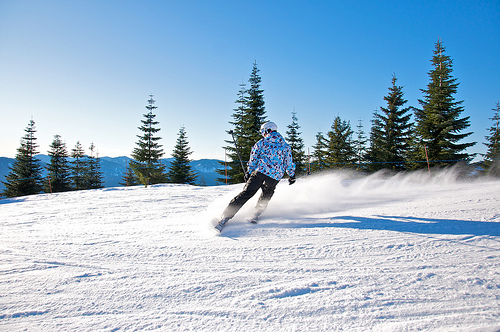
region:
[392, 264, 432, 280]
part of a snowy landscape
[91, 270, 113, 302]
part of a snowy surface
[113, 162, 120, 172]
section of a hilly land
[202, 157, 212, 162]
top part of a mountain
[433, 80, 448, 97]
leaves of a tree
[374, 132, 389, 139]
branches of a tree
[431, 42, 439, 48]
upper part of a tree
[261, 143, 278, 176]
back of a skater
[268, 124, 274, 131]
section of a white helmet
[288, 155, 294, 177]
right arm of a skater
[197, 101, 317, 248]
Person skiing.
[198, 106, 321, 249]
White helmet on skier's head.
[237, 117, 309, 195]
Blue, black, and grey ski jacket on skier.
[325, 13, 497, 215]
Clear blue sky.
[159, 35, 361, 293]
Evergreen trees in the background.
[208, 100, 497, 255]
Shadows on the snow.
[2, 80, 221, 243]
More mountains in the background.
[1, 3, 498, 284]
Winter time.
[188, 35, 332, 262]
Skier has ski poles.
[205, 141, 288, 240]
Skier wearing black pants.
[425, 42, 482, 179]
The color of the tree is a very deep green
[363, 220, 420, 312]
The color of the snow is a very bright white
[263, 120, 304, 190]
The skier is wearing a very bright blue and purple coat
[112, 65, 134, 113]
The sky has a light blue color that is rather crisp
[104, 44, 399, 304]
This photo was taken in the state of Colorado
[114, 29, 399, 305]
This photo was take outside the city of Denver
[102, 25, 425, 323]
This photo was taken in the season of Winter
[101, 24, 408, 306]
This photo was taken during the month of November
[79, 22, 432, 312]
Jason Zack is the person who took this photo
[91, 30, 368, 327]
This photo won a contest for being the best-conceived entry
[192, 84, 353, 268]
person is skiing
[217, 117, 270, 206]
person is holding ski pole in hand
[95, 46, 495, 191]
pine trees are in front of person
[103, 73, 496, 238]
pine trees are green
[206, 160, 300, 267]
person has on black pants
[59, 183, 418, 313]
snow is covering the ground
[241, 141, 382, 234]
person has on black gloves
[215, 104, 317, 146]
person's hat is white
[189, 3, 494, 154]
sky is blue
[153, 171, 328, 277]
person's leg is gliding against snow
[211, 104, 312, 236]
lone skier spraying snow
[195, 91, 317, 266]
single skier with poles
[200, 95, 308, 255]
downhill skier in blue jacket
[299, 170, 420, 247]
snow spray from skier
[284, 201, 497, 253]
elongated shadow of a skier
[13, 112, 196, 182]
evergreen trees growing on the side of a mountain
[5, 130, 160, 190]
mountains in the distance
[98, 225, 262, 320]
snow with ski tracks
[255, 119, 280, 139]
white skiing helmet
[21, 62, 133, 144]
morning sky with blue and white